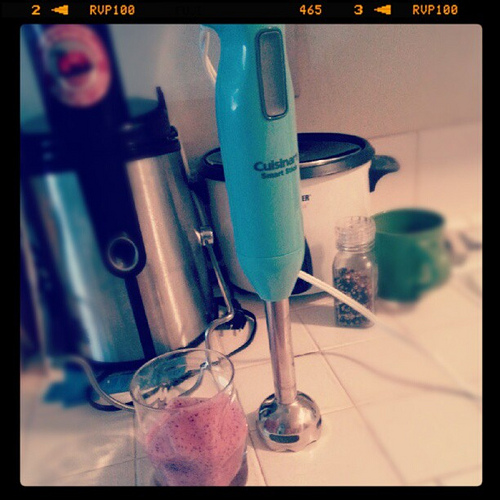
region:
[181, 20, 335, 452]
a teal green immerson blender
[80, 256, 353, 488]
pink smoothie next to an immersion blender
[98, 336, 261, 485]
berry smoothie in a clear glass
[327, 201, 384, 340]
clear plastic pepper grinder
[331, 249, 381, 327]
peppercorns in a jar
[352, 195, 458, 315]
a green mug on a kitchen counter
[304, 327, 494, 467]
white tiled kitchen counter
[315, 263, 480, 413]
electrical cord on a kitchen counter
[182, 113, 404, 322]
small white kitchen appliance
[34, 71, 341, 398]
electrical gadgets on a kitchen counter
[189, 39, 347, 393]
turquoise cuisine art mixer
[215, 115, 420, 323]
white crockpot with black handles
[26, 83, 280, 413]
silver and black small appliance on counter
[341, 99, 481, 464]
white tile counter extends to a low backsplash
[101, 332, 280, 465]
small glass with beverage on counter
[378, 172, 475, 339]
blue coffee mug on counter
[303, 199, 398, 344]
clear spice shaker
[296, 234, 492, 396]
white power cord to mixer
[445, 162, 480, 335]
corner of sink meeting counter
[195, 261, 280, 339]
plug for crockpot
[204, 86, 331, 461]
cuisinart handheld beater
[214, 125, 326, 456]
a blue handheld mixer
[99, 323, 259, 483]
glass with a lavender substance in it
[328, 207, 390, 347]
mostly full glass shaker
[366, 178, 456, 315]
green coffee mug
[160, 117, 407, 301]
small black and white slow cooker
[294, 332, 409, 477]
ceramic tiles on counter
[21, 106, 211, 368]
stainless steel and black juicer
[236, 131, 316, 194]
company logo on handheld mixer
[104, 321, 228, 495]
glass half full with purple liquid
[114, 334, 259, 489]
clear glass with pink drink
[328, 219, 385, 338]
clear plastic pepper shaker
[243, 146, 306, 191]
company name on side of mixer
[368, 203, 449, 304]
green coffee cup on counter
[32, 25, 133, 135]
design on front of appliance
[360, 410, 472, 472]
white counter top tile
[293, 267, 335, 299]
white electric cord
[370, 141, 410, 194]
black handle on slow cooker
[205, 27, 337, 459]
green electric mixer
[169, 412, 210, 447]
black seeds in pink drink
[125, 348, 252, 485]
a smoothie in a glass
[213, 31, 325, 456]
cuisinart kitchen tool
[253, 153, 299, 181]
cuisinart logo on a blue tool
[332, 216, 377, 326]
a plastic pepper grinder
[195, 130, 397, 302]
crockpot on a counter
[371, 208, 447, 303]
a green ceramic mug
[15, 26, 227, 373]
juicer on a counter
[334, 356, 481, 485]
tile countertop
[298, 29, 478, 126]
section of white wall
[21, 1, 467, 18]
information about the picture